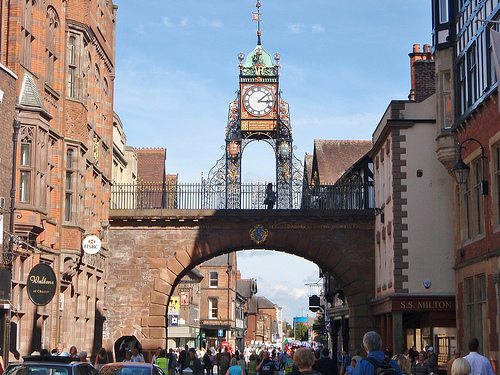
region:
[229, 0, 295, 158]
detailed round clock tower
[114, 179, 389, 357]
large brown brick bridge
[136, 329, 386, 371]
lots of people walking on the street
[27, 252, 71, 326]
round street black sign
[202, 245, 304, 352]
old brick buildings in the street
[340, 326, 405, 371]
man with gray hair and backpack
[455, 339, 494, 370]
man with white dress shirt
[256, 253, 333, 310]
blue sky with clouds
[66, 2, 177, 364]
tall brick building in the street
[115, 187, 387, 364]
there is part shade on the bridge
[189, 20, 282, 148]
a clock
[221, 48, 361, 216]
a clock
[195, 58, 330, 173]
a clock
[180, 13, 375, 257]
a clock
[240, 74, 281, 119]
the clock on the clock tower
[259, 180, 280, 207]
the girl standing on the bridge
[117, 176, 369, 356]
the big bridge in between the buildings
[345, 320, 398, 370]
the man watching the clock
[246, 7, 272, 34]
the flag on the pole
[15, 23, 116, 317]
the old buildings a side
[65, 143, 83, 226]
the windows of the builidng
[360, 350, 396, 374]
the black colored bag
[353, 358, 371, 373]
the blue colored shirt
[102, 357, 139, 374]
the car on the road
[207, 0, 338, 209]
A large clock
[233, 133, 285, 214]
archway under the clock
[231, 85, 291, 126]
clock face on the structure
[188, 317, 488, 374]
A large group of people walking in the street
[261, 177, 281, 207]
A person standing in front of the clock structure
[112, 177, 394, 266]
A bridge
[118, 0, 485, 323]
A clear, blue sky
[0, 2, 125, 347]
A large brick building in front of the bridge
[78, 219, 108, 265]
A business sign hanging down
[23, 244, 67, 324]
A business sign hanging down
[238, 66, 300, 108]
clock above the land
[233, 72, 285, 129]
white face of the clock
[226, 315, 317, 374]
people on the ground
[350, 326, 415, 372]
back of a man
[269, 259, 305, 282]
sky above the land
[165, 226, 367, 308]
brown arch way under bridge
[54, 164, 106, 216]
windows on the building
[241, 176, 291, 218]
person on a bridge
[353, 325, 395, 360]
man with gray hair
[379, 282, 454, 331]
word on the building